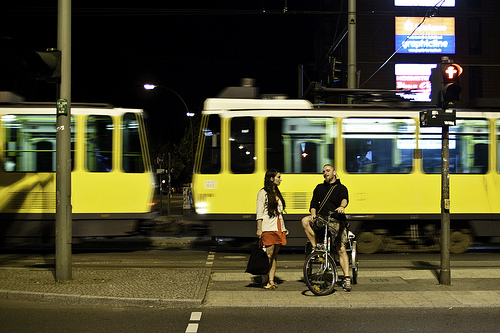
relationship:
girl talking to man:
[245, 160, 294, 292] [299, 163, 355, 293]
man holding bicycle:
[299, 163, 355, 293] [297, 208, 365, 298]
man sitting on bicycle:
[299, 163, 355, 293] [302, 212, 357, 294]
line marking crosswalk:
[184, 321, 198, 331] [180, 243, 485, 329]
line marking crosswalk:
[186, 308, 202, 322] [180, 243, 485, 329]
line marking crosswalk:
[203, 260, 213, 265] [180, 243, 485, 329]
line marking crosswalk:
[205, 252, 215, 259] [180, 243, 485, 329]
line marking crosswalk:
[209, 250, 216, 255] [180, 243, 485, 329]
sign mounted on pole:
[57, 97, 69, 119] [51, 0, 75, 287]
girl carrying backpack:
[243, 165, 293, 292] [243, 236, 273, 276]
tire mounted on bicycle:
[300, 249, 339, 297] [303, 205, 367, 295]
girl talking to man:
[243, 165, 293, 292] [299, 163, 355, 293]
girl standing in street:
[243, 165, 293, 292] [5, 239, 490, 331]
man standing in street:
[299, 163, 355, 293] [5, 239, 490, 331]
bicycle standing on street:
[267, 152, 379, 289] [5, 239, 490, 331]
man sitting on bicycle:
[299, 163, 355, 293] [267, 152, 379, 289]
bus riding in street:
[180, 74, 500, 261] [5, 239, 490, 331]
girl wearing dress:
[243, 165, 293, 292] [259, 193, 286, 245]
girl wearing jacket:
[243, 165, 293, 292] [254, 188, 289, 234]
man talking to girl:
[299, 163, 355, 293] [243, 165, 293, 292]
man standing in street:
[299, 163, 355, 293] [4, 226, 495, 331]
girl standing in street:
[243, 165, 293, 292] [4, 226, 495, 331]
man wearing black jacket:
[299, 163, 355, 293] [308, 177, 350, 220]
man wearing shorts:
[299, 163, 355, 293] [310, 211, 348, 248]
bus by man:
[180, 74, 500, 261] [299, 163, 355, 293]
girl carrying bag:
[243, 165, 293, 292] [242, 235, 273, 277]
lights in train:
[281, 118, 492, 134] [193, 101, 497, 251]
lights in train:
[288, 117, 489, 134] [193, 101, 497, 251]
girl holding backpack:
[243, 165, 293, 292] [243, 236, 273, 276]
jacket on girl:
[254, 188, 291, 233] [243, 165, 293, 292]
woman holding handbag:
[231, 129, 289, 331] [243, 241, 271, 277]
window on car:
[336, 112, 416, 177] [135, 103, 477, 258]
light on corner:
[421, 54, 467, 282] [8, 69, 498, 331]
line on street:
[181, 309, 204, 333] [5, 239, 490, 331]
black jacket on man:
[308, 178, 348, 223] [301, 163, 359, 291]